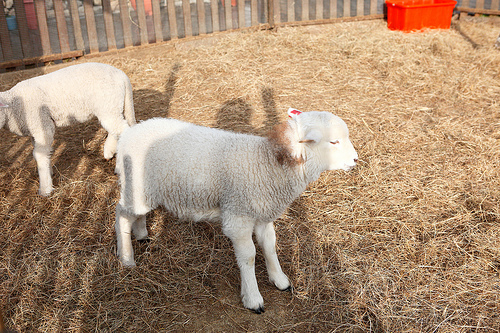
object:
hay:
[131, 284, 162, 295]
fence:
[0, 0, 109, 37]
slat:
[249, 0, 260, 27]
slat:
[181, 1, 193, 40]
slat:
[101, 0, 116, 47]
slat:
[341, 0, 352, 20]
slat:
[82, 2, 100, 54]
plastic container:
[383, 1, 457, 32]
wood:
[12, 8, 115, 38]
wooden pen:
[2, 4, 143, 44]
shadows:
[212, 95, 260, 127]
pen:
[0, 3, 206, 47]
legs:
[219, 196, 266, 314]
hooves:
[240, 271, 267, 315]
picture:
[7, 5, 497, 324]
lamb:
[0, 60, 138, 197]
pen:
[0, 0, 95, 65]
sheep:
[112, 106, 359, 316]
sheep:
[0, 60, 137, 199]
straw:
[386, 69, 498, 128]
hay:
[409, 206, 499, 233]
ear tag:
[287, 107, 306, 120]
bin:
[383, 0, 458, 34]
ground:
[368, 225, 493, 332]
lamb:
[112, 107, 360, 315]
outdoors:
[276, 1, 497, 82]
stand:
[112, 107, 358, 314]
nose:
[353, 157, 358, 162]